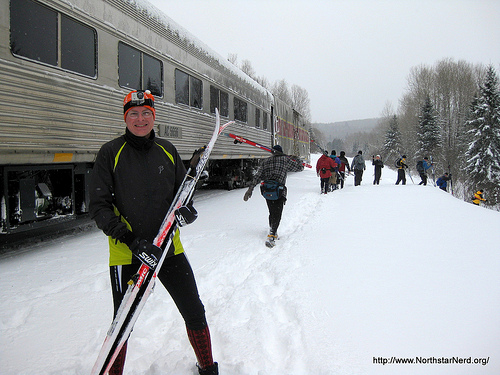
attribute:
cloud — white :
[353, 13, 498, 43]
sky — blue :
[303, 10, 401, 104]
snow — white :
[253, 285, 302, 325]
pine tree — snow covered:
[467, 63, 499, 200]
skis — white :
[128, 111, 231, 311]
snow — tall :
[310, 247, 442, 318]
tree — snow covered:
[462, 62, 499, 205]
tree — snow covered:
[414, 92, 443, 174]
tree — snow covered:
[380, 112, 407, 169]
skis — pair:
[87, 104, 239, 374]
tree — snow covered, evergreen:
[458, 65, 499, 202]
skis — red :
[219, 126, 312, 168]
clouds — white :
[332, 65, 367, 103]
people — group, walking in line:
[296, 114, 433, 224]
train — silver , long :
[41, 20, 287, 155]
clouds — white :
[288, 22, 360, 82]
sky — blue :
[287, 13, 382, 90]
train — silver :
[4, 6, 319, 208]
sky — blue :
[163, 0, 498, 129]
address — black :
[371, 356, 491, 366]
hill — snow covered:
[1, 138, 498, 370]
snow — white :
[410, 242, 460, 288]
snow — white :
[3, 144, 498, 374]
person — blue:
[404, 152, 435, 189]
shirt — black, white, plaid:
[248, 154, 304, 189]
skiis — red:
[227, 129, 313, 167]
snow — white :
[0, 0, 497, 374]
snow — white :
[305, 230, 447, 328]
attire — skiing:
[69, 105, 274, 369]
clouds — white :
[313, 28, 455, 176]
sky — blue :
[187, 7, 484, 121]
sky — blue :
[224, 22, 451, 132]